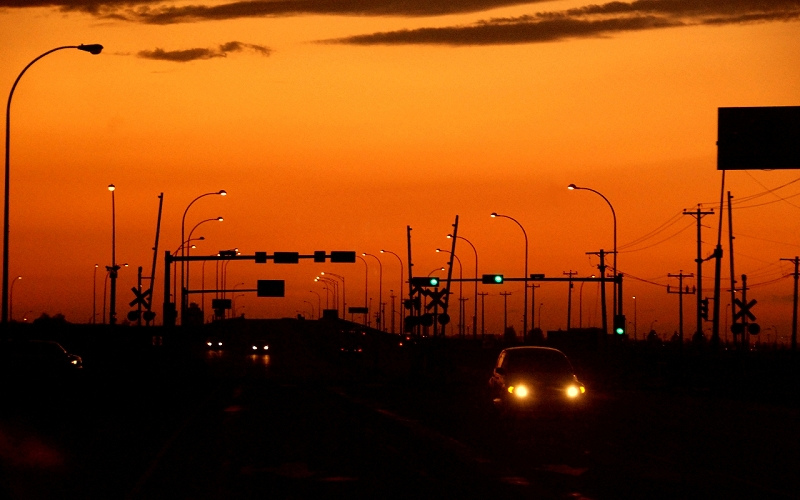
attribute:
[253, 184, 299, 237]
sky — orange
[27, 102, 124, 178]
sky — orange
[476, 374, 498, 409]
tire — rear